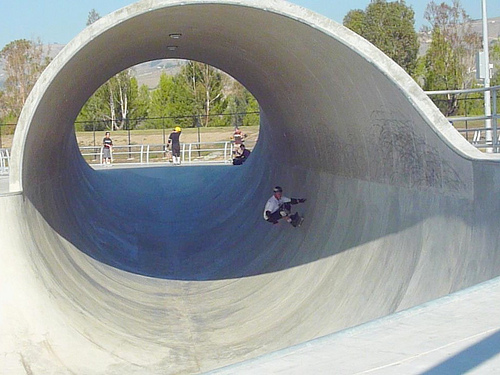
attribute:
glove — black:
[299, 197, 306, 203]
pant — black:
[267, 202, 315, 239]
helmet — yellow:
[171, 124, 183, 136]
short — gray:
[100, 146, 110, 159]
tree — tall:
[196, 72, 216, 144]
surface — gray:
[2, 2, 496, 367]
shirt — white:
[263, 194, 293, 214]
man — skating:
[262, 184, 305, 235]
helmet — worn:
[271, 184, 286, 195]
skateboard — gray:
[286, 213, 298, 227]